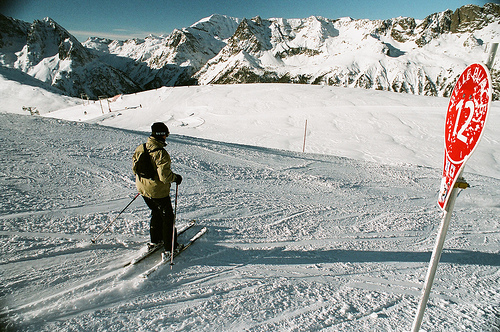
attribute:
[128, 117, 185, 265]
man — skiing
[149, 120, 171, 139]
cap — black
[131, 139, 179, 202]
jacket — tan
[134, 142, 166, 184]
backpack — black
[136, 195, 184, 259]
pants — long, black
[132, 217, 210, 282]
skis — black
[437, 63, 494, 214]
sign — red, round, white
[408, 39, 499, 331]
post — metal, white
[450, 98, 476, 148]
number — white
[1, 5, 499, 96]
mountains — white, brown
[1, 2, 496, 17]
sky — blue gray, blue